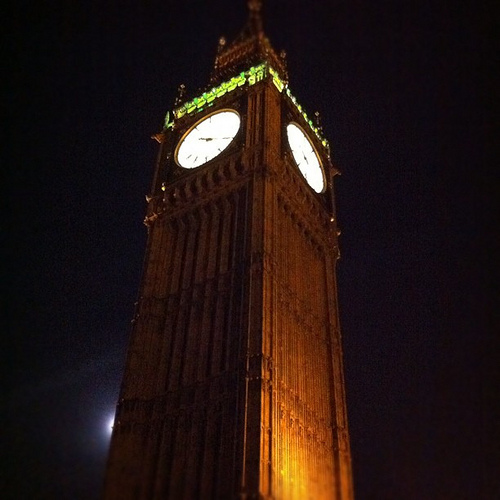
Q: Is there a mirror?
A: No, there are no mirrors.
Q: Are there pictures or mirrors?
A: No, there are no mirrors or pictures.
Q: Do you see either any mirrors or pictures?
A: No, there are no mirrors or pictures.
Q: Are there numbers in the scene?
A: Yes, there are numbers.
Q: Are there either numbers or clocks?
A: Yes, there are numbers.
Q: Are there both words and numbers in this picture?
A: No, there are numbers but no words.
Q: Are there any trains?
A: No, there are no trains.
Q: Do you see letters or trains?
A: No, there are no trains or letters.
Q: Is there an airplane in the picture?
A: No, there are no airplanes.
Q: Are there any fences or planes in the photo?
A: No, there are no planes or fences.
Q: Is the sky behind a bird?
A: No, the sky is behind the tower.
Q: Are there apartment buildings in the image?
A: No, there are no apartment buildings.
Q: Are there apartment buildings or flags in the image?
A: No, there are no apartment buildings or flags.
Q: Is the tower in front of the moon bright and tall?
A: Yes, the tower is bright and tall.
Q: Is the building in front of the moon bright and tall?
A: Yes, the tower is bright and tall.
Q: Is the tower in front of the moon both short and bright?
A: No, the tower is bright but tall.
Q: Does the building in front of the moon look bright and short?
A: No, the tower is bright but tall.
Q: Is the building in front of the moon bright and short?
A: No, the tower is bright but tall.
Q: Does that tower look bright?
A: Yes, the tower is bright.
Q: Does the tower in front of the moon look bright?
A: Yes, the tower is bright.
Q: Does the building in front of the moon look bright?
A: Yes, the tower is bright.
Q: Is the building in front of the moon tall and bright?
A: Yes, the tower is tall and bright.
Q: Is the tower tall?
A: Yes, the tower is tall.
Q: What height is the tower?
A: The tower is tall.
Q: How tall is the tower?
A: The tower is tall.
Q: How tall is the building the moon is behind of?
A: The tower is tall.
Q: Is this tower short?
A: No, the tower is tall.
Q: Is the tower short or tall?
A: The tower is tall.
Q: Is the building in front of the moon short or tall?
A: The tower is tall.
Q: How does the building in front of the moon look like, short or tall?
A: The tower is tall.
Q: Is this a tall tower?
A: Yes, this is a tall tower.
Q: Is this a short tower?
A: No, this is a tall tower.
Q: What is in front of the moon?
A: The tower is in front of the moon.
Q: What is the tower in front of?
A: The tower is in front of the moon.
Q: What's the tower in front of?
A: The tower is in front of the moon.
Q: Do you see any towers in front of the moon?
A: Yes, there is a tower in front of the moon.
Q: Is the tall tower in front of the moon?
A: Yes, the tower is in front of the moon.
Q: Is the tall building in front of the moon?
A: Yes, the tower is in front of the moon.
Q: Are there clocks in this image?
A: Yes, there is a clock.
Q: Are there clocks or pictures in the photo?
A: Yes, there is a clock.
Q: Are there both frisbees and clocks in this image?
A: No, there is a clock but no frisbees.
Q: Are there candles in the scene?
A: No, there are no candles.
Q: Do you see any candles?
A: No, there are no candles.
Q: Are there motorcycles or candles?
A: No, there are no candles or motorcycles.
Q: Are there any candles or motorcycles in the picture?
A: No, there are no candles or motorcycles.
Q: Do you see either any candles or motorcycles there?
A: No, there are no candles or motorcycles.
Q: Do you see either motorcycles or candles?
A: No, there are no candles or motorcycles.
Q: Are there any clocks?
A: Yes, there is a clock.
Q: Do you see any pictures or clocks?
A: Yes, there is a clock.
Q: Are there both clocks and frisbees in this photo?
A: No, there is a clock but no frisbees.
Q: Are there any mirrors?
A: No, there are no mirrors.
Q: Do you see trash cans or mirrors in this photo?
A: No, there are no mirrors or trash cans.